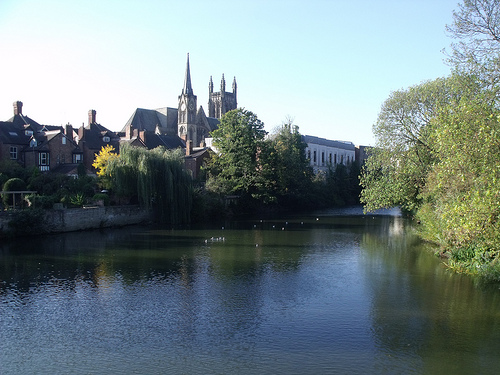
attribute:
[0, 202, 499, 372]
there is a lake. — clear, calm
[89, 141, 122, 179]
leaves are yellow. — bright yellow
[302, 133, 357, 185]
there is a building. — white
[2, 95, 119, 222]
house is near river — brown, brick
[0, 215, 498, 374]
water — green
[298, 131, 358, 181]
building — white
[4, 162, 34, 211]
bush — green, manicured, round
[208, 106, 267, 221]
tree — large, tall, green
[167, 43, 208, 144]
tower — tall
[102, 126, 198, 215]
tree — willow tree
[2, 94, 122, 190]
house — brown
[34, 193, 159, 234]
wall — brick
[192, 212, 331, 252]
birds — small, white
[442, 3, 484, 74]
tree — tall, green